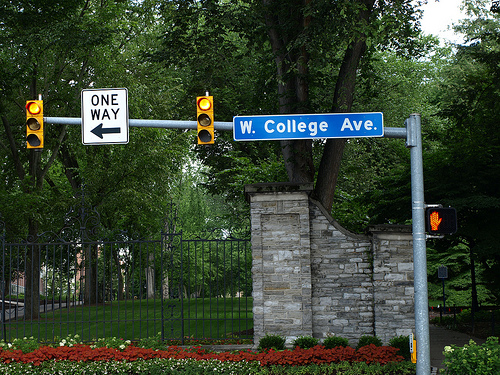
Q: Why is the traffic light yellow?
A: To make people slow down.